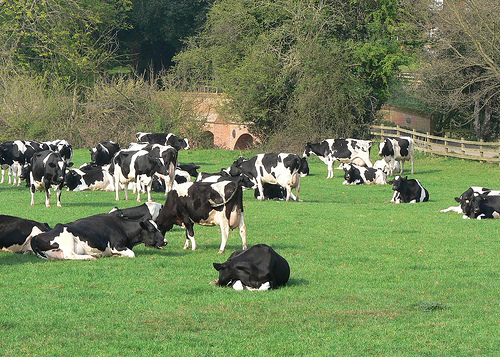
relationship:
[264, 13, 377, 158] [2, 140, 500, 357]
tree in field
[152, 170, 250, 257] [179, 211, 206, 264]
cow has legs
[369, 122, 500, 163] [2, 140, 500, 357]
bridge beside field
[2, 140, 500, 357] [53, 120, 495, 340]
field of grass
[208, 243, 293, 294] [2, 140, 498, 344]
cow in field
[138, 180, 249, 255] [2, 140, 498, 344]
cow in field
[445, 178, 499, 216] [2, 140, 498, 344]
cow in field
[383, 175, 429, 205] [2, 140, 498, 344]
cow in field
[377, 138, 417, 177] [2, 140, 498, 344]
cow in field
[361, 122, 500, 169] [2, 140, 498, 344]
fence along field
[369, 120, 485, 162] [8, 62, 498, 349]
bridge on backside of field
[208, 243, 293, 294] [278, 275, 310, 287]
cow has shadow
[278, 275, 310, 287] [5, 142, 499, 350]
shadow on grass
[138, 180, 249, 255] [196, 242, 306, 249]
cow has shadow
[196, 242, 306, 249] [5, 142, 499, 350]
shadow on grass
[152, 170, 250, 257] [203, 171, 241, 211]
cow swinging tail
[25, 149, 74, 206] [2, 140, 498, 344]
cow standing on field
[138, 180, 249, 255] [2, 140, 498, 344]
cow standing on field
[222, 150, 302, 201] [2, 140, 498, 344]
cow standing on field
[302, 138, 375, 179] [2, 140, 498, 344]
cow standing on field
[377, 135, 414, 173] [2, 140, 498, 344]
cow standing on field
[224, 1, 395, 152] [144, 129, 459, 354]
tree along field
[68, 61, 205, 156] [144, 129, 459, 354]
tree along field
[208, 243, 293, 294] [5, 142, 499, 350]
cow lying on grass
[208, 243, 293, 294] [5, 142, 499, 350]
cow on grass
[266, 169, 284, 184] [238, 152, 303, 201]
spot on cow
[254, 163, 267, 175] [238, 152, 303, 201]
spot on cow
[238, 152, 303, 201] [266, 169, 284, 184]
cow has spot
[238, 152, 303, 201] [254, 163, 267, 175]
cow has spot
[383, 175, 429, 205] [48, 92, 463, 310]
cow in field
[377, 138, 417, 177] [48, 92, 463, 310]
cow in field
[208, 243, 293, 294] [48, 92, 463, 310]
cow in field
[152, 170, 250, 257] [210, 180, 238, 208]
cow has cow's tail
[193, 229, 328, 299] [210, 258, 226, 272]
cow has ear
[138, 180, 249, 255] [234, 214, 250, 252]
cow has leg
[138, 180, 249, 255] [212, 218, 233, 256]
cow has leg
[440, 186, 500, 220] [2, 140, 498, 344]
cow on field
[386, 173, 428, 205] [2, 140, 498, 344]
cow on field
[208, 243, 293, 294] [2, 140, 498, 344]
cow on field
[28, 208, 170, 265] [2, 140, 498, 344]
cow on field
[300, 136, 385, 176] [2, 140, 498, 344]
cow on field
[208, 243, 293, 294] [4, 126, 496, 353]
cow on field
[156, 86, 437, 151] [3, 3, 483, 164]
bridge in background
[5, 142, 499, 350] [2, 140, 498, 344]
grass on field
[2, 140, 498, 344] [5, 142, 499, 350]
field has grass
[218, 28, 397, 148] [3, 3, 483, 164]
tree in background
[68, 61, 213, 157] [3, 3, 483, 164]
tree in background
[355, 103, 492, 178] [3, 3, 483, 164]
fence in background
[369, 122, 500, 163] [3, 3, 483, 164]
bridge in background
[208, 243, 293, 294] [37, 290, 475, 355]
cow on grass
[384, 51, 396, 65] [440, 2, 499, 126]
leaf on bare tree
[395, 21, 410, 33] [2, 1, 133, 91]
leaf on tree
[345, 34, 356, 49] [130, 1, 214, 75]
leaf on tree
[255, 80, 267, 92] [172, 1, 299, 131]
leaf on tree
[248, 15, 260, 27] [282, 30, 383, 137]
leaf on tree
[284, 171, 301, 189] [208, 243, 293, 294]
udder on cow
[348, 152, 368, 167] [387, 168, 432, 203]
udder on cow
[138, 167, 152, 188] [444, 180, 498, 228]
udder on cow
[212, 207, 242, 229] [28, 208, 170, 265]
udder on cow